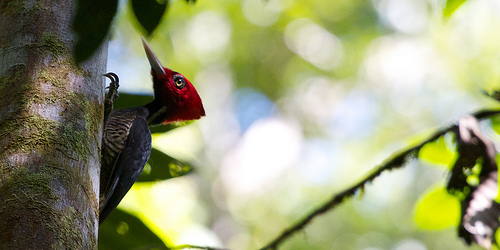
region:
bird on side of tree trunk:
[82, 4, 211, 237]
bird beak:
[131, 30, 166, 76]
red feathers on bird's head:
[146, 63, 214, 133]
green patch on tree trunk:
[5, 113, 82, 165]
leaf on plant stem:
[436, 113, 498, 248]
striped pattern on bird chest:
[103, 100, 139, 164]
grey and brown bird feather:
[99, 112, 159, 228]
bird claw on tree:
[102, 63, 119, 118]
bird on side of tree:
[100, 18, 216, 231]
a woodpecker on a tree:
[23, 7, 455, 219]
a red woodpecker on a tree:
[78, 19, 216, 226]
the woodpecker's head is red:
[135, 37, 207, 134]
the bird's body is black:
[107, 80, 169, 224]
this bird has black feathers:
[104, 92, 164, 204]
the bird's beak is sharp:
[136, 31, 176, 74]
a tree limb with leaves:
[261, 106, 497, 246]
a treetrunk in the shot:
[12, 5, 107, 220]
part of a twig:
[418, 110, 430, 138]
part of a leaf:
[481, 150, 492, 175]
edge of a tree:
[256, 196, 257, 198]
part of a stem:
[91, 129, 99, 138]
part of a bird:
[117, 145, 118, 157]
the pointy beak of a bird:
[138, 38, 163, 74]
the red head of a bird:
[150, 67, 207, 129]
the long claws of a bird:
[105, 72, 118, 104]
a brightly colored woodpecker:
[101, 28, 207, 227]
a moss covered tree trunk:
[1, 0, 108, 248]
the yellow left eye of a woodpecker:
[175, 76, 185, 86]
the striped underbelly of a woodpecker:
[102, 111, 131, 170]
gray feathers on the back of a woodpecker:
[100, 118, 151, 220]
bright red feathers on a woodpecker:
[150, 65, 208, 117]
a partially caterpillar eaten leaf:
[133, 145, 195, 189]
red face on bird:
[153, 72, 210, 139]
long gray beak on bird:
[133, 36, 156, 77]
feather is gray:
[113, 123, 138, 218]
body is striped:
[96, 113, 133, 170]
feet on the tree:
[87, 61, 122, 118]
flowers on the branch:
[401, 121, 498, 248]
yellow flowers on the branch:
[401, 144, 457, 235]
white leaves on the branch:
[466, 129, 499, 249]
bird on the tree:
[0, 1, 95, 239]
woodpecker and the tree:
[0, 42, 237, 247]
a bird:
[102, 37, 217, 192]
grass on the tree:
[15, 170, 65, 235]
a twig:
[324, 183, 363, 207]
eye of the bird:
[172, 77, 188, 89]